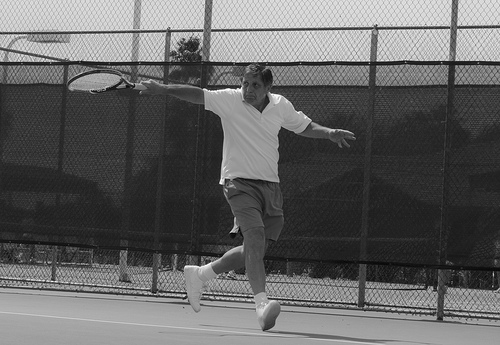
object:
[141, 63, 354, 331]
man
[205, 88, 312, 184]
shirt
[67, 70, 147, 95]
tennis racquet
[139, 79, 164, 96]
hand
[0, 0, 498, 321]
fence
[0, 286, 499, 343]
tennis court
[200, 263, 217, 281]
sock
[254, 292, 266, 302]
sock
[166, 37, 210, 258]
tree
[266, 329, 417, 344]
shadow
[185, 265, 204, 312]
foot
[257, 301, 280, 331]
foot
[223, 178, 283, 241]
shorts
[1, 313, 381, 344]
serving line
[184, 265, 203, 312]
shoe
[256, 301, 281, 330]
shoe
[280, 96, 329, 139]
left arm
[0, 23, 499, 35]
top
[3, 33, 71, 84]
light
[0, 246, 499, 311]
next court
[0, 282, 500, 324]
bottom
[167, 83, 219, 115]
right arm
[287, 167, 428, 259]
house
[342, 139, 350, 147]
fingers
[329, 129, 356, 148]
left hand